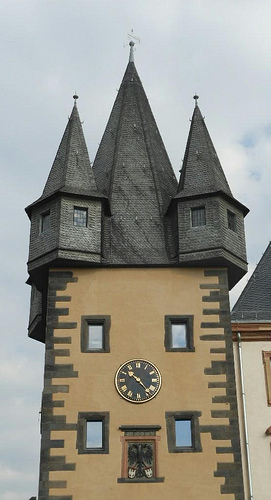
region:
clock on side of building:
[105, 349, 168, 407]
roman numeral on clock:
[133, 391, 142, 401]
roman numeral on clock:
[134, 361, 141, 369]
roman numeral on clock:
[149, 376, 159, 383]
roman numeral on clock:
[117, 376, 128, 384]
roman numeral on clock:
[126, 362, 132, 369]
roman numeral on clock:
[143, 363, 151, 369]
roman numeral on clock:
[149, 385, 157, 392]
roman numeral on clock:
[120, 383, 126, 391]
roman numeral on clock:
[126, 389, 134, 396]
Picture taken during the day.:
[29, 101, 224, 498]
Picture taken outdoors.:
[14, 109, 268, 465]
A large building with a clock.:
[20, 110, 263, 487]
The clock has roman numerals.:
[109, 352, 163, 407]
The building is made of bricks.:
[52, 281, 240, 285]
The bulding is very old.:
[24, 119, 202, 492]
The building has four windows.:
[74, 310, 218, 454]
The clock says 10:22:
[109, 356, 174, 403]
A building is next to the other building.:
[241, 268, 264, 421]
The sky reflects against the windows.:
[80, 316, 215, 470]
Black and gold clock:
[112, 356, 163, 405]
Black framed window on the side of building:
[75, 408, 109, 455]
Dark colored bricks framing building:
[210, 359, 233, 374]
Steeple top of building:
[93, 60, 177, 191]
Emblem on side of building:
[118, 434, 159, 483]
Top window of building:
[162, 313, 195, 352]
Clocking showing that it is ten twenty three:
[113, 358, 163, 404]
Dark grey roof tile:
[106, 136, 159, 187]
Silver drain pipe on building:
[235, 332, 254, 499]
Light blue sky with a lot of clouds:
[231, 123, 264, 172]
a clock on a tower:
[110, 355, 165, 407]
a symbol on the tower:
[112, 421, 172, 489]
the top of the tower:
[119, 32, 149, 63]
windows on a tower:
[162, 404, 206, 455]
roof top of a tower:
[5, 32, 254, 272]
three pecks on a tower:
[61, 30, 224, 118]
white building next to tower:
[220, 335, 269, 384]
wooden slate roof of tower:
[112, 127, 157, 210]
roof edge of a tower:
[61, 181, 112, 201]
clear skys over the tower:
[165, 24, 250, 92]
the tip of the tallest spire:
[127, 31, 145, 76]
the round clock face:
[113, 356, 156, 399]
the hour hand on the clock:
[122, 368, 140, 380]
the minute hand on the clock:
[137, 376, 154, 398]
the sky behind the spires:
[15, 7, 252, 190]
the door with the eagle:
[119, 418, 164, 486]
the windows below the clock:
[79, 406, 204, 454]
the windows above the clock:
[77, 318, 197, 353]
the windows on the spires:
[37, 207, 243, 234]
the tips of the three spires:
[62, 36, 207, 112]